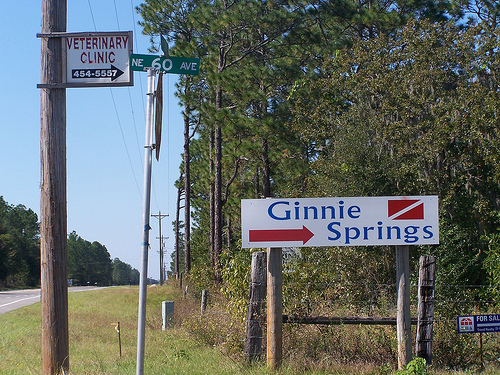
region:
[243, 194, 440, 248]
white sign on wood posts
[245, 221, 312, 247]
red arrow on white sign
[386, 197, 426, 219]
red block on sign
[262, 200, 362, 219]
blue writing on sign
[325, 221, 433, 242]
blue writing on sign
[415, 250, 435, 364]
wood post in ground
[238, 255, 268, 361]
wood post in ground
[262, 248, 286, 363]
wood post in ground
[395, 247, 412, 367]
wood post in ground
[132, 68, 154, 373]
metal post on ground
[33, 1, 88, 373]
A wooden pole in the foreground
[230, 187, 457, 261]
White sign has a red direction arrow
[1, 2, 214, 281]
The sky is clear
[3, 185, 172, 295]
Tall trees in the background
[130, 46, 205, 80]
A green street sign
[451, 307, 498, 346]
A blue for sale sign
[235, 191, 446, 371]
Poles holding sign are made of wood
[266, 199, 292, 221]
the letter G on a sign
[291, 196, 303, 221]
the letter i on a sign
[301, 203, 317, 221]
the letter n on a sign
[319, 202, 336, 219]
the letter n on a sign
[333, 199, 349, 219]
the letter i on a sign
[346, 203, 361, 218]
the letter e on a sign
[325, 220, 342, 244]
the letter S on a sign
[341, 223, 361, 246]
the letter p on a sign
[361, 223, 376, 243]
the letter r on a sign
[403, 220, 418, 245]
the letter g on a sign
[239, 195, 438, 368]
Posting on the side of the road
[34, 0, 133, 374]
Wooden pole on the side of the road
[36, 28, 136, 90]
Posting for a clinic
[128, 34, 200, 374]
Stop sign on the side of the road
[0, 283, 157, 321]
Road way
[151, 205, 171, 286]
Electrical wire on the side of the road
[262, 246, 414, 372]
Wooden poles beneath the sign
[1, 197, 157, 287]
Group of green trees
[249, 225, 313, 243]
Arrow on the post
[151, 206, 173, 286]
electrical pole in the grass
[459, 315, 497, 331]
sign on the pole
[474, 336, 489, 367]
pole attached to the sign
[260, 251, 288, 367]
pole attached to sign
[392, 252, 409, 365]
pole attached to sign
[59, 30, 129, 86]
sign on the pole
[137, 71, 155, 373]
pole attached to sign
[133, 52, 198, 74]
sign attached to pole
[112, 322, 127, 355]
stick in the grass